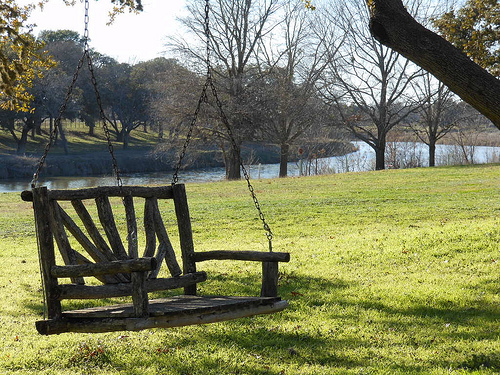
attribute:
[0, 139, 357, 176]
bank — long, river bank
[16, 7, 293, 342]
seat — swing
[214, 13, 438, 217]
trees — in the distance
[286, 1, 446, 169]
tree — bare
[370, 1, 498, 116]
branch — brown, tree branch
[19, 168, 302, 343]
chair — swinging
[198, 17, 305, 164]
trees — bare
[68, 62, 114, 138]
tree — in the distance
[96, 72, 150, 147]
tree — in the distance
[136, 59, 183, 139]
tree — in the distance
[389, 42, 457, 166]
tree — in the distance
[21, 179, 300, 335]
chair — swinging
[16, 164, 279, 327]
bench — wooden, swinging, gray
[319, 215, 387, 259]
grass — vgreen, short